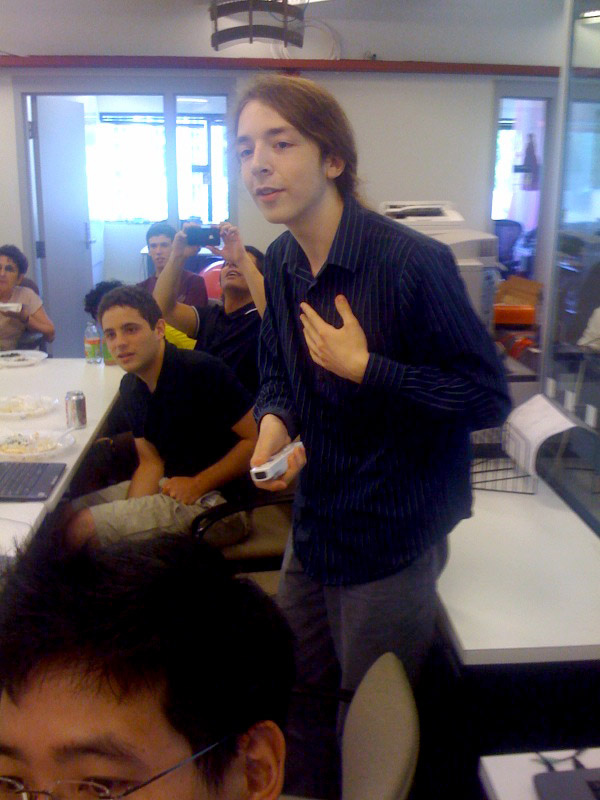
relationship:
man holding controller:
[220, 70, 504, 703] [247, 438, 301, 484]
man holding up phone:
[151, 224, 277, 328] [150, 226, 258, 382]